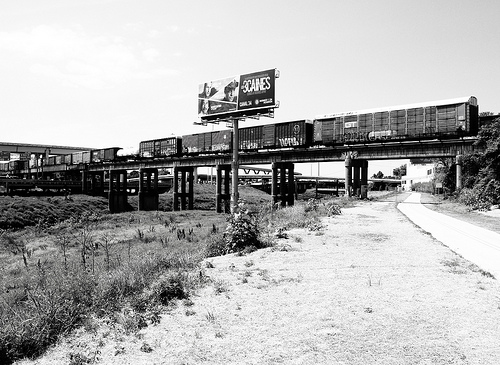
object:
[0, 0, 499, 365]
photo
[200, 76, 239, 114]
black and white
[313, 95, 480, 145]
train car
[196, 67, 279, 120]
billboard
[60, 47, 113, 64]
air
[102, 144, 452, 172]
bridge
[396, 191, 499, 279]
road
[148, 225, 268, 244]
grass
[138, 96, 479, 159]
row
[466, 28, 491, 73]
clouds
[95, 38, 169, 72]
sky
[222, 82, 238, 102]
people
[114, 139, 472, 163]
tracks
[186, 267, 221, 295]
dirt and weeds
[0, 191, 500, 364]
ground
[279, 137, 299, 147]
graffiti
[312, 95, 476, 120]
white roof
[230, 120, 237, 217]
pole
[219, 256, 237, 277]
sand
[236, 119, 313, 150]
train cars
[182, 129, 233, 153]
cargo